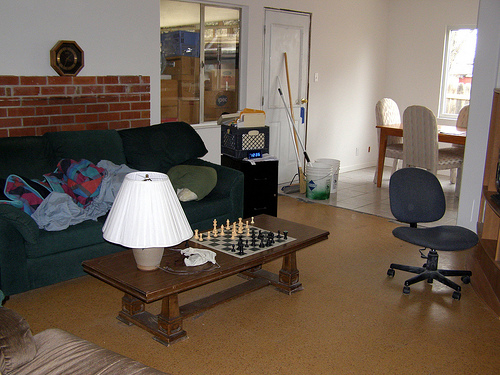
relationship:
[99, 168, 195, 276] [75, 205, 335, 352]
lamp on table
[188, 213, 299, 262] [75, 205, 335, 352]
game on table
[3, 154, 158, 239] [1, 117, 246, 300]
clothes on sofa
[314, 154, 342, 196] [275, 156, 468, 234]
buckets on floor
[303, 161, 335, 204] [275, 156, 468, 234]
buckets on floor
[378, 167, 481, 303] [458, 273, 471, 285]
chair has wheels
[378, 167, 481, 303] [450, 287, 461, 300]
chair has wheels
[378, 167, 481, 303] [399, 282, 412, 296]
chair has wheels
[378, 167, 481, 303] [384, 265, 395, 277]
chair has wheels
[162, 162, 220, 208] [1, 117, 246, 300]
pillow on sofa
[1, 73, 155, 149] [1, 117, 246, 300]
wall behind sofa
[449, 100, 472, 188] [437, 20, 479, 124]
chair by window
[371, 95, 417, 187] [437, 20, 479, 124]
chair by window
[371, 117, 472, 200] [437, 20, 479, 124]
table by window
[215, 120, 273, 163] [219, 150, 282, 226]
crate on cabinet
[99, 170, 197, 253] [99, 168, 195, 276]
shade of lamp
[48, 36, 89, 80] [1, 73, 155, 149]
clock on wall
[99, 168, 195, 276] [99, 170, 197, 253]
lamp with shade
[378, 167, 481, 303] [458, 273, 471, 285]
chair with wheels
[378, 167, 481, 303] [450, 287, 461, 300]
chair with wheels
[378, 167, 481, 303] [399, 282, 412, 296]
chair with wheels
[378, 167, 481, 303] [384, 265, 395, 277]
chair with wheels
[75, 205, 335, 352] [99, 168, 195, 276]
table with lamp